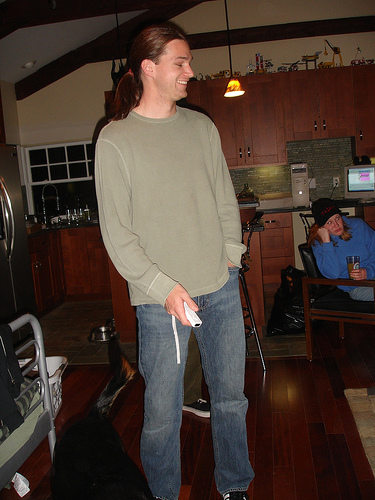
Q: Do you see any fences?
A: No, there are no fences.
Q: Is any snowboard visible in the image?
A: No, there are no snowboards.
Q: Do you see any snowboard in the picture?
A: No, there are no snowboards.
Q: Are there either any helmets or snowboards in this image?
A: No, there are no snowboards or helmets.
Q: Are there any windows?
A: Yes, there is a window.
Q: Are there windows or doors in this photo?
A: Yes, there is a window.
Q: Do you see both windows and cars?
A: No, there is a window but no cars.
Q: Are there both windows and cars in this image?
A: No, there is a window but no cars.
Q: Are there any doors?
A: No, there are no doors.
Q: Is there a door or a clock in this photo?
A: No, there are no doors or clocks.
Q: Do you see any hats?
A: Yes, there is a hat.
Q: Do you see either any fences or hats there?
A: Yes, there is a hat.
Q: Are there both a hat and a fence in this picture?
A: No, there is a hat but no fences.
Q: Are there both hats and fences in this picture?
A: No, there is a hat but no fences.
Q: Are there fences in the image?
A: No, there are no fences.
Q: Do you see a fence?
A: No, there are no fences.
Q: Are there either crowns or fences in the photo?
A: No, there are no fences or crowns.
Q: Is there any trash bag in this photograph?
A: Yes, there is a trash bag.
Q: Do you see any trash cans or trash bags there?
A: Yes, there is a trash bag.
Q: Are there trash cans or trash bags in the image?
A: Yes, there is a trash bag.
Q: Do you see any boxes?
A: No, there are no boxes.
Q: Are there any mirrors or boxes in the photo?
A: No, there are no boxes or mirrors.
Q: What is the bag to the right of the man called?
A: The bag is a trash bag.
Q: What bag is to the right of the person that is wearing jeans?
A: The bag is a trash bag.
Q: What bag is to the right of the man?
A: The bag is a trash bag.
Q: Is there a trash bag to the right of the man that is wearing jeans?
A: Yes, there is a trash bag to the right of the man.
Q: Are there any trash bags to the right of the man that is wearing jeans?
A: Yes, there is a trash bag to the right of the man.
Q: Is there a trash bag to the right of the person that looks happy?
A: Yes, there is a trash bag to the right of the man.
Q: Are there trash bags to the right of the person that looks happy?
A: Yes, there is a trash bag to the right of the man.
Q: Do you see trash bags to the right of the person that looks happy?
A: Yes, there is a trash bag to the right of the man.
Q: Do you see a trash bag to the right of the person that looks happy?
A: Yes, there is a trash bag to the right of the man.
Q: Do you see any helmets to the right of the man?
A: No, there is a trash bag to the right of the man.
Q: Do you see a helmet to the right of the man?
A: No, there is a trash bag to the right of the man.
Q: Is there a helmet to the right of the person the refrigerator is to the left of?
A: No, there is a trash bag to the right of the man.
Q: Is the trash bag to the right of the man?
A: Yes, the trash bag is to the right of the man.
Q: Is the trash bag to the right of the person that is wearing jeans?
A: Yes, the trash bag is to the right of the man.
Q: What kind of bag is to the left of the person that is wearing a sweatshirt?
A: The bag is a trash bag.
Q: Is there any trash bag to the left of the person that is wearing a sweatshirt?
A: Yes, there is a trash bag to the left of the person.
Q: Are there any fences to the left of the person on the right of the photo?
A: No, there is a trash bag to the left of the person.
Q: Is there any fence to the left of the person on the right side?
A: No, there is a trash bag to the left of the person.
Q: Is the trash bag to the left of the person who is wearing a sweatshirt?
A: Yes, the trash bag is to the left of the person.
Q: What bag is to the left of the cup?
A: The bag is a trash bag.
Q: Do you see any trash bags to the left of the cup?
A: Yes, there is a trash bag to the left of the cup.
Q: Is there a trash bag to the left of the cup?
A: Yes, there is a trash bag to the left of the cup.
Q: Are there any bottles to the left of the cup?
A: No, there is a trash bag to the left of the cup.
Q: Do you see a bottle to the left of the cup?
A: No, there is a trash bag to the left of the cup.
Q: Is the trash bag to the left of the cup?
A: Yes, the trash bag is to the left of the cup.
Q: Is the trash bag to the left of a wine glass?
A: No, the trash bag is to the left of the cup.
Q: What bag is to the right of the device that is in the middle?
A: The bag is a trash bag.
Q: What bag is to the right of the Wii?
A: The bag is a trash bag.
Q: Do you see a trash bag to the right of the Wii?
A: Yes, there is a trash bag to the right of the Wii.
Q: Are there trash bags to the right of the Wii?
A: Yes, there is a trash bag to the right of the Wii.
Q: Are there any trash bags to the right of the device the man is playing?
A: Yes, there is a trash bag to the right of the Wii.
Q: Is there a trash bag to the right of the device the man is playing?
A: Yes, there is a trash bag to the right of the Wii.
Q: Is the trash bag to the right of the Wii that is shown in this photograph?
A: Yes, the trash bag is to the right of the Wii.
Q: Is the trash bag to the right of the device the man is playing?
A: Yes, the trash bag is to the right of the Wii.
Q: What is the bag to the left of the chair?
A: The bag is a trash bag.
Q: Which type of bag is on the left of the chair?
A: The bag is a trash bag.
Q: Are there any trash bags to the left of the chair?
A: Yes, there is a trash bag to the left of the chair.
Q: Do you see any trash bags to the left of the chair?
A: Yes, there is a trash bag to the left of the chair.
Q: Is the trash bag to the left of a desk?
A: No, the trash bag is to the left of a chair.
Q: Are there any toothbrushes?
A: No, there are no toothbrushes.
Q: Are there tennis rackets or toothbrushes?
A: No, there are no toothbrushes or tennis rackets.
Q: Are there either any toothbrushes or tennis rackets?
A: No, there are no toothbrushes or tennis rackets.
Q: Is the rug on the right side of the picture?
A: Yes, the rug is on the right of the image.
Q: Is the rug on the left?
A: No, the rug is on the right of the image.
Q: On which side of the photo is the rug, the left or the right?
A: The rug is on the right of the image.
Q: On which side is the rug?
A: The rug is on the right of the image.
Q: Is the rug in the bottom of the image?
A: Yes, the rug is in the bottom of the image.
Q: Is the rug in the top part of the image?
A: No, the rug is in the bottom of the image.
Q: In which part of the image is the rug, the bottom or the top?
A: The rug is in the bottom of the image.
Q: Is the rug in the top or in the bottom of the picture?
A: The rug is in the bottom of the image.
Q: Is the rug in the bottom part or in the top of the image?
A: The rug is in the bottom of the image.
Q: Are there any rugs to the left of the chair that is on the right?
A: Yes, there is a rug to the left of the chair.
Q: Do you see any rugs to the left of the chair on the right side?
A: Yes, there is a rug to the left of the chair.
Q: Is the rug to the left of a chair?
A: Yes, the rug is to the left of a chair.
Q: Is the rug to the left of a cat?
A: No, the rug is to the left of a chair.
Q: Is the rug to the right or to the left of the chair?
A: The rug is to the left of the chair.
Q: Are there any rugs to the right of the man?
A: Yes, there is a rug to the right of the man.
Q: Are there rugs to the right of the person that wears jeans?
A: Yes, there is a rug to the right of the man.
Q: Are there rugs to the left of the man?
A: No, the rug is to the right of the man.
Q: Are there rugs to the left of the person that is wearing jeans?
A: No, the rug is to the right of the man.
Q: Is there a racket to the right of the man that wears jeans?
A: No, there is a rug to the right of the man.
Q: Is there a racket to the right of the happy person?
A: No, there is a rug to the right of the man.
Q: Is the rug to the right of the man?
A: Yes, the rug is to the right of the man.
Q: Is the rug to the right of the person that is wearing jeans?
A: Yes, the rug is to the right of the man.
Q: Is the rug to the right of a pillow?
A: No, the rug is to the right of the man.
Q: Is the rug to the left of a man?
A: No, the rug is to the right of a man.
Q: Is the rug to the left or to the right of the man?
A: The rug is to the right of the man.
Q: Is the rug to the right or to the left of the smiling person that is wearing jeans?
A: The rug is to the right of the man.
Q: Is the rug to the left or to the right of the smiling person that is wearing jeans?
A: The rug is to the right of the man.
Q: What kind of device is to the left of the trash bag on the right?
A: The device is a Wii.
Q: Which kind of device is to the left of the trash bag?
A: The device is a Wii.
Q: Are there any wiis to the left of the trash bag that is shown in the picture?
A: Yes, there is a Wii to the left of the trash bag.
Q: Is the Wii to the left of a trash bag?
A: Yes, the Wii is to the left of a trash bag.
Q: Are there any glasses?
A: No, there are no glasses.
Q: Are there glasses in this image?
A: No, there are no glasses.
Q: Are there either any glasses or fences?
A: No, there are no glasses or fences.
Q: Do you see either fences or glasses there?
A: No, there are no glasses or fences.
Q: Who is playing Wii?
A: The man is playing wii.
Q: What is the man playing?
A: The man is playing wii.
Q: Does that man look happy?
A: Yes, the man is happy.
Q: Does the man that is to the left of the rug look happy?
A: Yes, the man is happy.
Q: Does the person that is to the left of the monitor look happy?
A: Yes, the man is happy.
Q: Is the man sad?
A: No, the man is happy.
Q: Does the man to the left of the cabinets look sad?
A: No, the man is happy.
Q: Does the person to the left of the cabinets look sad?
A: No, the man is happy.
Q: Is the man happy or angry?
A: The man is happy.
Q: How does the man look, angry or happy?
A: The man is happy.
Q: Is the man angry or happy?
A: The man is happy.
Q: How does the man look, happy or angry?
A: The man is happy.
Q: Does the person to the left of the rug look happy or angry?
A: The man is happy.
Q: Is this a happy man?
A: Yes, this is a happy man.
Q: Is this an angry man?
A: No, this is a happy man.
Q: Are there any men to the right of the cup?
A: No, the man is to the left of the cup.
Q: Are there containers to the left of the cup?
A: No, there is a man to the left of the cup.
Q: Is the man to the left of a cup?
A: Yes, the man is to the left of a cup.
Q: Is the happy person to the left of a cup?
A: Yes, the man is to the left of a cup.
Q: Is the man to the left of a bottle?
A: No, the man is to the left of a cup.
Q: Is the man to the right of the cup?
A: No, the man is to the left of the cup.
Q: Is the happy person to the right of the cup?
A: No, the man is to the left of the cup.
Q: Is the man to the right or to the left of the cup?
A: The man is to the left of the cup.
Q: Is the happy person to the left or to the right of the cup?
A: The man is to the left of the cup.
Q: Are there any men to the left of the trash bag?
A: Yes, there is a man to the left of the trash bag.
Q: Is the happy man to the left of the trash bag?
A: Yes, the man is to the left of the trash bag.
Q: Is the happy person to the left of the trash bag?
A: Yes, the man is to the left of the trash bag.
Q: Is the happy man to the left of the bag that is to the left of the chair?
A: Yes, the man is to the left of the trash bag.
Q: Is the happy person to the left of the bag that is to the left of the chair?
A: Yes, the man is to the left of the trash bag.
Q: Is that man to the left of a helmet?
A: No, the man is to the left of the trash bag.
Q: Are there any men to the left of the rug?
A: Yes, there is a man to the left of the rug.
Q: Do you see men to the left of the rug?
A: Yes, there is a man to the left of the rug.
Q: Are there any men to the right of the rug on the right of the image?
A: No, the man is to the left of the rug.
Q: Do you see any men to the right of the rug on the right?
A: No, the man is to the left of the rug.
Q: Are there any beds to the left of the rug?
A: No, there is a man to the left of the rug.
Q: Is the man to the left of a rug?
A: Yes, the man is to the left of a rug.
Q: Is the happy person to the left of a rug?
A: Yes, the man is to the left of a rug.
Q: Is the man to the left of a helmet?
A: No, the man is to the left of a rug.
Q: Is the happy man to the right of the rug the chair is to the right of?
A: No, the man is to the left of the rug.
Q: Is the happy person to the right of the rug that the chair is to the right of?
A: No, the man is to the left of the rug.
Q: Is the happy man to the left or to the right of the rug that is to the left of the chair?
A: The man is to the left of the rug.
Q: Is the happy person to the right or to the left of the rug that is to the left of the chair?
A: The man is to the left of the rug.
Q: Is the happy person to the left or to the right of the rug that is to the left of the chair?
A: The man is to the left of the rug.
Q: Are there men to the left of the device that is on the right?
A: Yes, there is a man to the left of the monitor.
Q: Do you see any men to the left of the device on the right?
A: Yes, there is a man to the left of the monitor.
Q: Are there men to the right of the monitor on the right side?
A: No, the man is to the left of the monitor.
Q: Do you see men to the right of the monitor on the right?
A: No, the man is to the left of the monitor.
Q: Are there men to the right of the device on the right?
A: No, the man is to the left of the monitor.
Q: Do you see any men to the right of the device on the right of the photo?
A: No, the man is to the left of the monitor.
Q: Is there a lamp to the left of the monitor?
A: No, there is a man to the left of the monitor.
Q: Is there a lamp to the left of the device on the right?
A: No, there is a man to the left of the monitor.